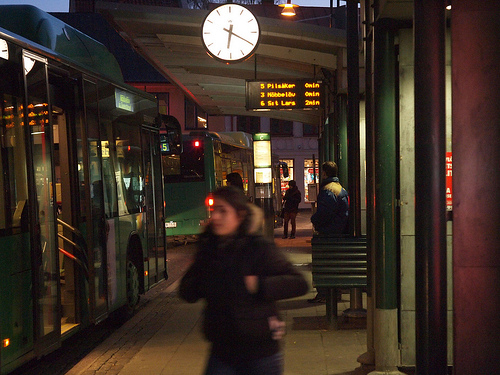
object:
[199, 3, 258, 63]
clock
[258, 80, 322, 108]
writing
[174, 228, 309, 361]
jacket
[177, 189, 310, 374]
girl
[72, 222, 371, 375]
sidewalk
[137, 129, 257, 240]
bus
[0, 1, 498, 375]
picture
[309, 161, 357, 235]
man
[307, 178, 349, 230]
jacket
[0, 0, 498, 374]
terminal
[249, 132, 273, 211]
display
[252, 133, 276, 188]
routes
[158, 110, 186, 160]
mirror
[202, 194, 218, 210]
lights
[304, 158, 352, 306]
waiting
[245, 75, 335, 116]
schedule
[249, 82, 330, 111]
times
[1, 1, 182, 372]
bus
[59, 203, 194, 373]
curb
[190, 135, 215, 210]
lights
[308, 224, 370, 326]
bench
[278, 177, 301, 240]
passengers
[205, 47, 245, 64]
portion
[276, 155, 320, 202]
lights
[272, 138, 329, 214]
stores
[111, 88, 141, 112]
destination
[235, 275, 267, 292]
hands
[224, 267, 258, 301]
pocket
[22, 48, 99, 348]
door